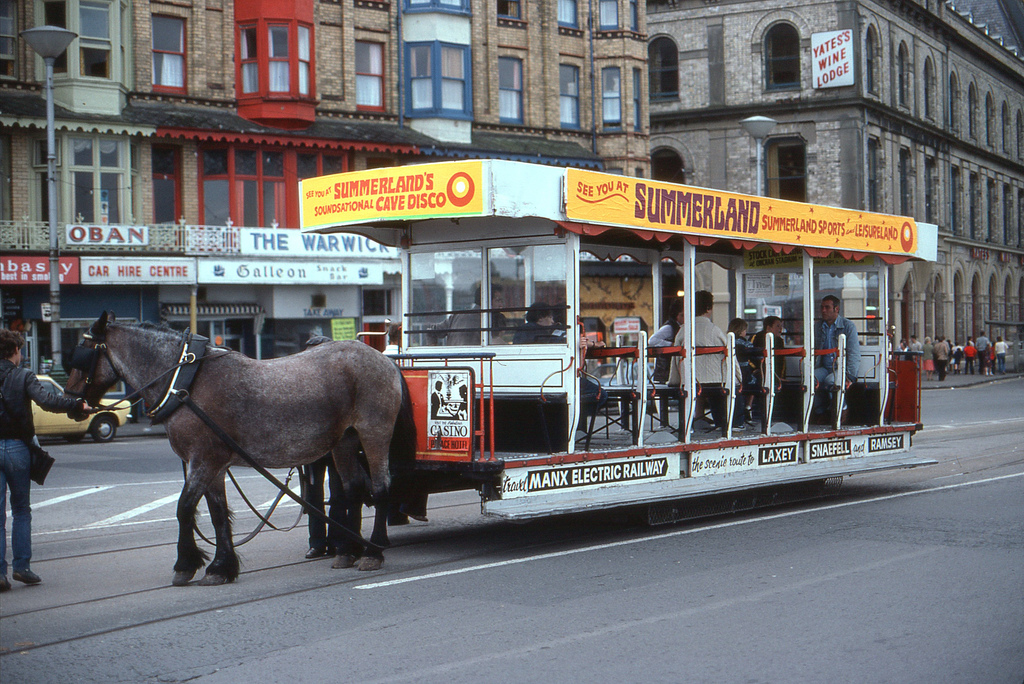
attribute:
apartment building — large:
[19, 5, 307, 215]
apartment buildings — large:
[339, 3, 646, 151]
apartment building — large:
[321, 3, 639, 148]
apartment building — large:
[265, 13, 648, 160]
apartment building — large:
[153, 5, 653, 153]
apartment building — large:
[36, 3, 646, 148]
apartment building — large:
[62, 5, 648, 170]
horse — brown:
[82, 307, 420, 576]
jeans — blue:
[11, 448, 38, 587]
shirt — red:
[959, 335, 977, 359]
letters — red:
[815, 40, 846, 80]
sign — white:
[806, 31, 859, 98]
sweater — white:
[677, 312, 734, 382]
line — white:
[359, 511, 815, 589]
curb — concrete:
[921, 366, 1014, 399]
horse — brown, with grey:
[55, 296, 455, 601]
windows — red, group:
[129, 89, 464, 265]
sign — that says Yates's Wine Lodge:
[811, 26, 866, 102]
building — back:
[662, 6, 985, 402]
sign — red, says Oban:
[58, 209, 147, 246]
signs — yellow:
[300, 145, 946, 260]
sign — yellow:
[293, 147, 499, 243]